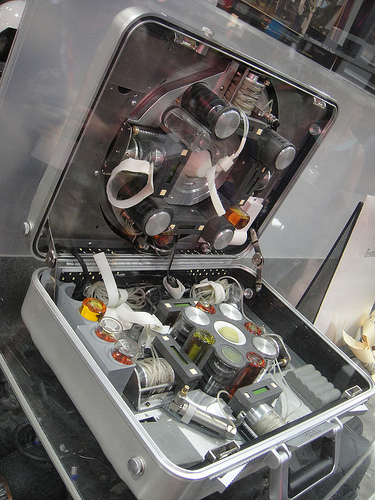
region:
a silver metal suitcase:
[9, 259, 297, 497]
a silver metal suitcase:
[17, 281, 161, 465]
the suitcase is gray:
[17, 278, 169, 489]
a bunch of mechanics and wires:
[84, 220, 318, 430]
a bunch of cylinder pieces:
[174, 304, 280, 380]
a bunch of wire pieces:
[136, 352, 166, 402]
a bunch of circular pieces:
[278, 362, 335, 414]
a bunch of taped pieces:
[96, 148, 153, 220]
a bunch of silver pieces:
[114, 429, 160, 484]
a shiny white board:
[307, 192, 355, 271]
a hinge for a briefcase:
[11, 223, 72, 286]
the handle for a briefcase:
[253, 435, 355, 484]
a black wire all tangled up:
[9, 413, 71, 483]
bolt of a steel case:
[16, 210, 32, 240]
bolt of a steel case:
[113, 455, 147, 488]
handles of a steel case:
[258, 407, 351, 494]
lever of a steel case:
[340, 406, 371, 425]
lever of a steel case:
[179, 456, 262, 496]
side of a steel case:
[11, 260, 182, 498]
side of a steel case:
[9, 11, 160, 254]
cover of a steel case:
[35, 1, 338, 280]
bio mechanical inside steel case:
[102, 62, 340, 447]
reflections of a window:
[316, 9, 362, 57]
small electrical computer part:
[232, 367, 285, 409]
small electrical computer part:
[210, 338, 246, 397]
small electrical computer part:
[247, 325, 286, 363]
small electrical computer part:
[209, 311, 252, 347]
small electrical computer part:
[100, 324, 149, 374]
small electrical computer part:
[180, 291, 212, 334]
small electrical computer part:
[218, 291, 249, 323]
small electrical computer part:
[123, 188, 180, 248]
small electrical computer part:
[194, 200, 240, 255]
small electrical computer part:
[92, 138, 163, 220]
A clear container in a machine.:
[218, 324, 236, 345]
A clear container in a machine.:
[249, 336, 273, 353]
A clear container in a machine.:
[222, 301, 237, 318]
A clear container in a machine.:
[180, 311, 210, 330]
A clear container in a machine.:
[112, 342, 143, 364]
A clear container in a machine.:
[97, 317, 122, 343]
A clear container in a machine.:
[82, 297, 99, 315]